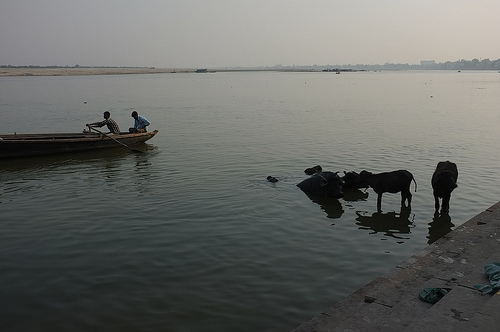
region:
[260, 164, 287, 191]
small stone in water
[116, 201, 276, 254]
small line in calm waters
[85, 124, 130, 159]
oars on small boat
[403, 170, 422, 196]
tail on the cow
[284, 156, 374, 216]
large cluster of rocks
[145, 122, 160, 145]
edge of small boat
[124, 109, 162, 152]
man sitting in boat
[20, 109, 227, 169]
small boat in water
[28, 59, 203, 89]
large land in the distance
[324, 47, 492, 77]
many houses on land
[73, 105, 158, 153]
two men in a boat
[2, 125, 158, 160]
the boat is long and narrow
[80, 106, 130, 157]
a man is rowing a boat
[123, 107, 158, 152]
a man is sitting in the back of the boat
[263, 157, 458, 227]
cows are dipping in the river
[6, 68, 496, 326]
the river is flat and gray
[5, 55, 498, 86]
trees and buildings are in the distance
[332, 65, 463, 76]
boats are on the horizon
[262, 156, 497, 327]
the cows are next to cement steps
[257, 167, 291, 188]
a cow swimming in the river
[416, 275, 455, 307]
a pair of sandals on the stairs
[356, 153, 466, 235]
two cows in the water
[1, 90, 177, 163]
two men rowing a boat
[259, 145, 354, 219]
trash floating in the water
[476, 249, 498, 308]
clothes on the stairs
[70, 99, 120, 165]
the man rowing the boat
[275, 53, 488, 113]
view of the city in the distance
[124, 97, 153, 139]
a man sitting on the boat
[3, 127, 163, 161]
the boat the two men are sitting on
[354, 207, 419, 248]
the reflection of one cow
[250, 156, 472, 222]
four cows in the water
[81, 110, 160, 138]
two people in a boat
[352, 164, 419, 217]
a baby cow looking at an adult cow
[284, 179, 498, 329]
cement retaining wall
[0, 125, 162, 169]
a long wooden boat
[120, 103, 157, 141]
a man wearing a blue shirt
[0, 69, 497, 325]
a lot of very calm water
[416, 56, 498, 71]
a cluster of buildings by the lake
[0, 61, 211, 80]
the opposite sandy shore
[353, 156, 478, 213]
two small black cows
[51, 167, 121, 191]
Green and blue water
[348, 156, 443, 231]
Cow in water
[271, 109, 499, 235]
Group of cows in water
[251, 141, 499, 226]
Group of cows drinking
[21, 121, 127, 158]
Brown row boat in water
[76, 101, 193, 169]
Two people on a row boat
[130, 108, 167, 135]
Man in a blue shirt on a boat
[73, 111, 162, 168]
Man rowing a boat in water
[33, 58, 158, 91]
Brown land next to water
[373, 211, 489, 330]
Gray stairs by water